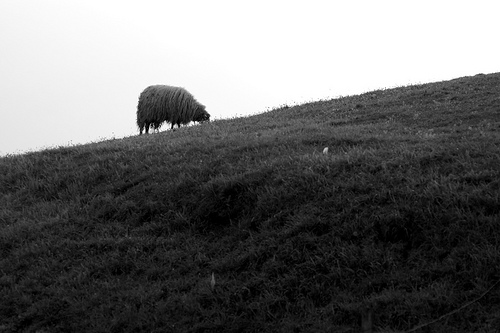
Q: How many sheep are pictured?
A: One.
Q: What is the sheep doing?
A: Grazing.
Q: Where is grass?
A: On a hill.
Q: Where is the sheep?
A: On the hillside.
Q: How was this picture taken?
A: Using black and white photography.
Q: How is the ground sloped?
A: Uphill from left to right.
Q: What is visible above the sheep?
A: The sky.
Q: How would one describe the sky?
A: Clear.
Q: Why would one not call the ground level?
A: It has mounds and recessed areas.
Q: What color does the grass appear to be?
A: Gray.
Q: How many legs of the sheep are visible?
A: Four.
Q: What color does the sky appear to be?
A: White.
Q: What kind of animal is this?
A: Sheep.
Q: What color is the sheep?
A: White.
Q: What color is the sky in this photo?
A: White and off white.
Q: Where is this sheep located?
A: Top of hill.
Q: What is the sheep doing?
A: Grazing.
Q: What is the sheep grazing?
A: Grass.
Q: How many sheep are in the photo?
A: One.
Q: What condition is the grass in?
A: Healthy and manicured.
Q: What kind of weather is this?
A: Cloudy.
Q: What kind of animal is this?
A: Sheep.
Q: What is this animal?
A: It is a sheep.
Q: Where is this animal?
A: On a mountain side.